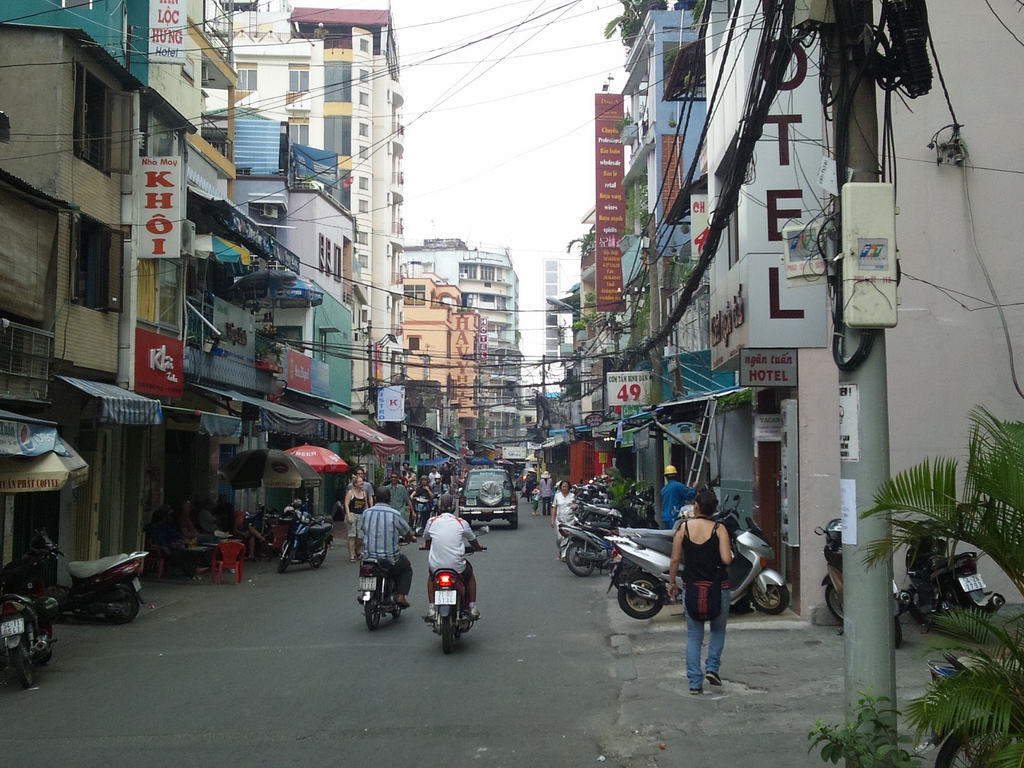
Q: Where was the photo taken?
A: City street.